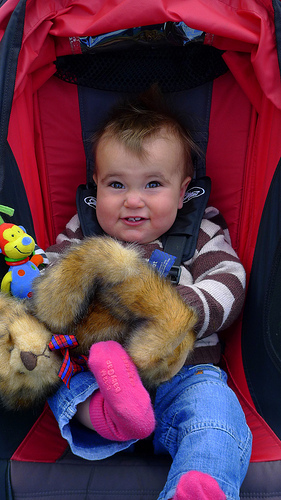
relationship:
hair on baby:
[95, 86, 200, 159] [49, 91, 256, 499]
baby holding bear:
[49, 91, 256, 499] [0, 233, 196, 408]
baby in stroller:
[49, 91, 256, 499] [2, 3, 279, 498]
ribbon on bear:
[50, 335, 83, 383] [0, 233, 196, 408]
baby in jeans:
[49, 91, 256, 499] [48, 358, 254, 497]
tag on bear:
[148, 250, 178, 273] [0, 233, 196, 408]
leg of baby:
[161, 376, 251, 498] [49, 91, 256, 499]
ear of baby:
[181, 174, 196, 210] [49, 91, 256, 499]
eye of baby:
[141, 177, 166, 189] [49, 91, 256, 499]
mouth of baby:
[117, 212, 152, 225] [49, 91, 256, 499]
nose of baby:
[125, 188, 145, 210] [49, 91, 256, 499]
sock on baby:
[84, 339, 158, 443] [49, 91, 256, 499]